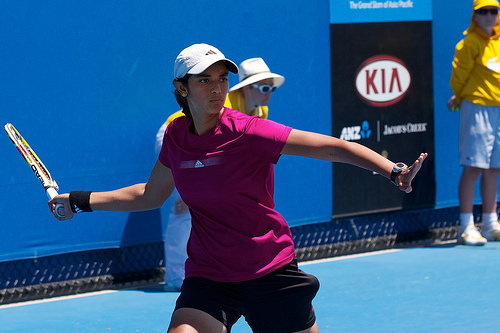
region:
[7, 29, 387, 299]
woman holding a tennis racket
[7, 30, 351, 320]
woman wearing a pink shirt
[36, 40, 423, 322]
woman wearing black shorts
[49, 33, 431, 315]
woman wearing Adidas baseball hat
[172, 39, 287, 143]
man wearing yellow shirt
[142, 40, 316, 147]
man wearing a white hat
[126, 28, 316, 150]
man wearing white sunglasses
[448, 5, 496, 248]
man wearing yellow sweatshirt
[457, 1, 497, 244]
man wearing yellow baseball hat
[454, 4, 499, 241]
man wearing gray shorts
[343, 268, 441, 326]
the floor is blue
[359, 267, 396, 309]
the floor is blue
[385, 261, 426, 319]
the floor is blue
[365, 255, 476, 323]
the floor is blue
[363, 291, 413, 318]
the floor is blue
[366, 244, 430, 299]
the floor is blue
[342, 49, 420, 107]
Advertisement on the wall of tennis court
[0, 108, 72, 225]
Tennis racket used by tennis player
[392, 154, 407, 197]
Wristwatch worn by tennis player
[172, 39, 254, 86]
Baseball hat worn by tennis player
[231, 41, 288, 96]
Line judge for a tennis game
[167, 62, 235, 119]
Look of concentration on tennis players face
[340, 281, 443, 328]
Blue surface on a tennis court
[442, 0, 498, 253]
Ballboy at a tennis game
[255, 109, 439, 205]
Tennis players arm extended for balance and power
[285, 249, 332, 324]
Ball in pocket of tennis player shorts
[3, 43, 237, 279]
woman holding a tennis racket with her right hand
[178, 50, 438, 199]
woman holding her left arm in front of her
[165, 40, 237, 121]
woman wearing a white ball cap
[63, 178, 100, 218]
thick black band on woman's right wrist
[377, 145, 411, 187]
watch on woman's left wrist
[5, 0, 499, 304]
blue wall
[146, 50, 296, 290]
person bending forward with their back to the wall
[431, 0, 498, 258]
person standing close to wall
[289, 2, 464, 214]
advertisement on wall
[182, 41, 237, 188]
identical logos on woman's hat and top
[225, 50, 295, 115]
White hat being worn by woman bending over.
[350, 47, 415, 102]
Red and white KIA decal.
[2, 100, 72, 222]
Tennis racket being held by player.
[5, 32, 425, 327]
Tennis player swinging tennis racket.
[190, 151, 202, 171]
White triangle on tennis players shirt.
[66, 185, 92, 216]
Black wristband worn by tennis player.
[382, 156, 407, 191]
Black and chrome watch being worn by tennis player.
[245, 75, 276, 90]
White sunglasses being worn by woman bending over.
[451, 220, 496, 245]
White and yellow shoes being worn by woman standing straight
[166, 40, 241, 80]
Light colored cap being worn by tennis player.